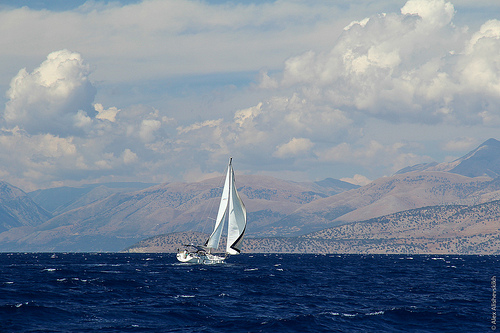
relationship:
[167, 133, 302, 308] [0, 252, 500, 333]
sailboat in blue water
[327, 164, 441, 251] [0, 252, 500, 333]
mountains beyond blue water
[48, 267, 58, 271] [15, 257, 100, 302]
white cap on wave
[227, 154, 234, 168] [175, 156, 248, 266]
metal tip on sailboat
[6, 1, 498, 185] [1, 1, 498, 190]
clouds in sky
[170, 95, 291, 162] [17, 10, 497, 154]
clouds in sky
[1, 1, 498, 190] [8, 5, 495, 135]
sky with clouds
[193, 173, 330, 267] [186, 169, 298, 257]
lining on a sail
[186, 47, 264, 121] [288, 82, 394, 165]
sky peeking through clouds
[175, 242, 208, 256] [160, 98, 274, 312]
people are sailing on a boat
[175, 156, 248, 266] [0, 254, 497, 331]
sailboat sailing on ocean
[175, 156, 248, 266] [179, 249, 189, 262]
sailboat carrying person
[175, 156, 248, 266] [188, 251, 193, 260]
sailboat carrying person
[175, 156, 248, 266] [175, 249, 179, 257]
sailboat carrying person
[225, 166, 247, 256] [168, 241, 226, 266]
sail on boat